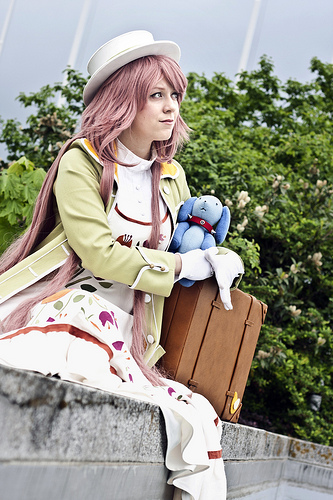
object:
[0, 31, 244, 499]
girl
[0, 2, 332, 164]
sky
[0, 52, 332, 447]
trees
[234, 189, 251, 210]
flowers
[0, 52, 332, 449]
bush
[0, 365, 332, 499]
wall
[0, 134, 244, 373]
coat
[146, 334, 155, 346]
buttons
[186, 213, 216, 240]
collar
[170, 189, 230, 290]
animal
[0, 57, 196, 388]
hair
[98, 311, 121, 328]
flowers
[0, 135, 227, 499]
dress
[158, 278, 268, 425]
suitcase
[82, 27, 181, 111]
hat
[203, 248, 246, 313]
gloves